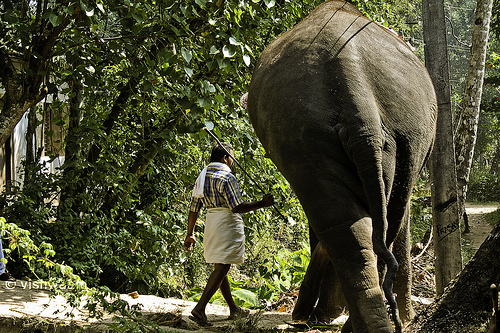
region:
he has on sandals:
[183, 278, 286, 330]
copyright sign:
[4, 273, 19, 299]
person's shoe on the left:
[0, 259, 18, 284]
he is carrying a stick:
[136, 88, 331, 229]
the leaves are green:
[121, 29, 225, 111]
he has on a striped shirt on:
[167, 155, 277, 236]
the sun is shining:
[264, 248, 343, 328]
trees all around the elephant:
[415, 120, 482, 217]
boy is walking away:
[171, 147, 276, 245]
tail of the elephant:
[322, 110, 430, 267]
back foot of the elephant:
[316, 232, 406, 330]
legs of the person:
[182, 250, 257, 323]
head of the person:
[203, 127, 239, 173]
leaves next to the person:
[70, 191, 176, 264]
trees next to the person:
[51, 87, 198, 217]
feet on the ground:
[187, 285, 262, 331]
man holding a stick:
[130, 140, 275, 330]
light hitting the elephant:
[305, 15, 362, 70]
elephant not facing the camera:
[254, 3, 455, 256]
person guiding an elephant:
[188, 11, 443, 332]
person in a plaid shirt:
[187, 132, 257, 332]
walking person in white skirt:
[186, 138, 251, 325]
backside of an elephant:
[255, 3, 438, 330]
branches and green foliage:
[74, 7, 181, 268]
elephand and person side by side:
[183, 4, 440, 331]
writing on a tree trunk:
[425, 188, 467, 255]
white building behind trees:
[2, 38, 120, 233]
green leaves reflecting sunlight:
[212, 31, 261, 74]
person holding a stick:
[193, 125, 287, 327]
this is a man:
[181, 144, 266, 288]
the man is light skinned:
[245, 198, 272, 214]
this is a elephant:
[276, 23, 446, 247]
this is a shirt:
[208, 173, 231, 193]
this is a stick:
[204, 132, 248, 171]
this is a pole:
[408, 8, 460, 139]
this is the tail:
[356, 155, 406, 231]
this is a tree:
[58, 53, 153, 224]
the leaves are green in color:
[71, 51, 95, 73]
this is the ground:
[27, 298, 92, 329]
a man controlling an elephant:
[61, 0, 488, 330]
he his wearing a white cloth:
[156, 152, 303, 331]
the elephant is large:
[239, 10, 429, 330]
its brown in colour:
[251, 0, 456, 327]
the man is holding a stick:
[127, 84, 291, 300]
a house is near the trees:
[5, 60, 73, 177]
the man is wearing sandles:
[168, 116, 334, 331]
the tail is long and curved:
[363, 113, 437, 331]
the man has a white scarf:
[160, 123, 263, 238]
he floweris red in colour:
[72, 239, 185, 308]